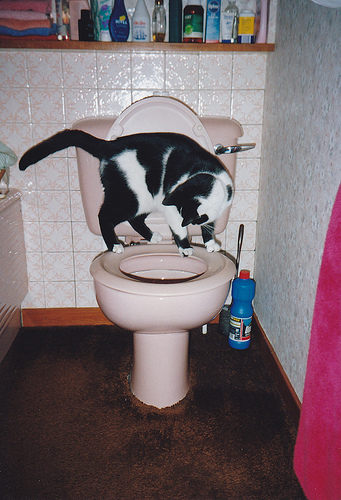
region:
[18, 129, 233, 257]
Cat is white and black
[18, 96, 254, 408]
Cat standing on toilet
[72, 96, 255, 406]
The toilet is pink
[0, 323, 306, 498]
The floor is brown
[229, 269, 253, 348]
A bottle of something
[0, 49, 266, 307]
Tiles on the wall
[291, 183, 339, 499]
Pink towel hangs down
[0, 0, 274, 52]
A shelf of stuff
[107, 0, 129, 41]
The bottle is blue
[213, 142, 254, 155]
Handle is silver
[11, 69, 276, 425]
A black and white cat standing on a toilet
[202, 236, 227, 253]
A cat's white paw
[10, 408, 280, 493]
A brown carpeted floor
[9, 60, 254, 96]
A pink and white tiled bathroom wall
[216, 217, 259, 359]
A bottle of toilet cleaner and a toilet brush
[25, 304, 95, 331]
A brown wooden baseboard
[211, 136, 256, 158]
A silver metal toilet handle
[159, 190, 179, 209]
A cat's right ear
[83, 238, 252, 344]
A pink porcelain toilet bowl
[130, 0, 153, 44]
A bottle of Old Spice aftershave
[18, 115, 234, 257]
the cat on the toilet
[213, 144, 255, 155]
the handle on the toilet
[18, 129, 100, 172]
the tail on the cat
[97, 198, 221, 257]
the four legs on the cat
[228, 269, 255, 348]
the bottle next to the toilet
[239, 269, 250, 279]
the red cap on the bottle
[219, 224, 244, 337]
the toilet brush cleaner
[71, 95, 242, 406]
the light pink toilet bowl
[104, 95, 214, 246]
the toilet seat cover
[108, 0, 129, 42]
the blue bottle on the shelf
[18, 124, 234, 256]
Black and white cat standing on a toilet seat.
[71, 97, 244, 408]
A pink toilet.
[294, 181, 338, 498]
The side of a red bath towel.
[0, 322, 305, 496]
Brown carpet on the floor.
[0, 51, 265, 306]
Pink and white wall tile.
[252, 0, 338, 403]
Floral wallpaper on the wall.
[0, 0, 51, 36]
Folded towels on top of the shelf.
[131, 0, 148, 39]
White bottle of aftershave sitting on the shelf.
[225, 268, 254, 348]
Blue bottle with a red lid sitting on the floor.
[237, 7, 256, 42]
White powder bottle with a yellow label.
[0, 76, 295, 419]
cat standing on toilet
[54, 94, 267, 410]
toilet is off white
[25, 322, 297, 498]
dark brown carpet on floor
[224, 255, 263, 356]
blue bottle on floor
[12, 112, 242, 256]
cat is black and white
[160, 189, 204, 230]
cat has black ears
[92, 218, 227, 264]
cat has white paws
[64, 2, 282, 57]
multiple items on shelf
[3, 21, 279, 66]
shelf is brown and wooden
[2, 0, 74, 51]
items folded on shelf